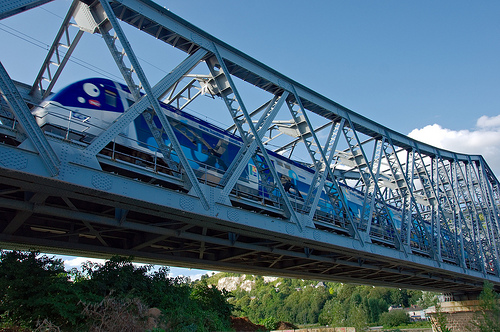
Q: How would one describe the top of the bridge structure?
A: Curved beam.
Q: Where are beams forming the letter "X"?
A: Side of bridge.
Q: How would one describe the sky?
A: Mostly clear.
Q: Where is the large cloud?
A: Behind the bridge.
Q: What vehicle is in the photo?
A: A train.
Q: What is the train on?
A: A bridge.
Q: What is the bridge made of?
A: Metal.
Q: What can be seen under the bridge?
A: Trees.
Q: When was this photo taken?
A: In the daytime.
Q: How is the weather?
A: Sunny.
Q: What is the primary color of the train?
A: Blue.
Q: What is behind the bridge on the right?
A: Clouds.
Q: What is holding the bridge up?
A: Concrete pillars.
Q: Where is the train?
A: On bridge.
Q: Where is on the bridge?
A: Train.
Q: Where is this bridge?
A: Over water.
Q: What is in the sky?
A: Clouds.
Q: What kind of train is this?
A: Modern.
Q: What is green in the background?
A: Trees.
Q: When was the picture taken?
A: Daytime.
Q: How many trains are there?
A: One.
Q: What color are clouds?
A: White.